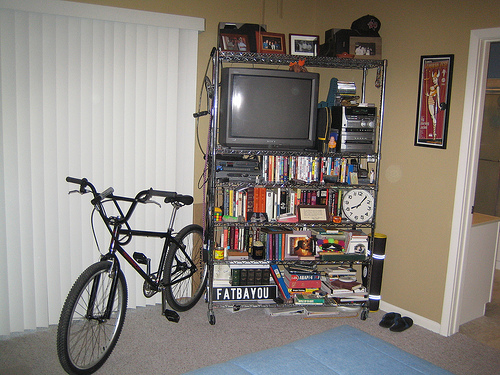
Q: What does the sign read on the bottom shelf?
A: Fatbayou.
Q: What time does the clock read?
A: Eight.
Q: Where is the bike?
A: On the left of the TV stand.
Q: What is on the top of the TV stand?
A: Picture frames.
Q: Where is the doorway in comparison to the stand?
A: On the right.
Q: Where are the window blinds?
A: Behind the bike.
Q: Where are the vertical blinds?
A: Covering the sliding door.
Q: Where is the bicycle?
A: In front of the door.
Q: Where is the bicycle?
A: In the living room.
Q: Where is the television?
A: In the corner on the cluttered shelf.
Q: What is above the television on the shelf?
A: Framed photos.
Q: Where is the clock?
A: On the shelf under the television.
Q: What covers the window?
A: Blinds.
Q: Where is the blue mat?
A: On the floor.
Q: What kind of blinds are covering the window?
A: Vertical blinds.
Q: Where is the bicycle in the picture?
A: In front of the window.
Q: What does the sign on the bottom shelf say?
A: FATBAYOU.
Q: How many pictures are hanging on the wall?
A: One.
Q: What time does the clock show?
A: 8:05.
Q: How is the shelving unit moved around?
A: With the wheels at the bottom of the unit.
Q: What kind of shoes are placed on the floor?
A: Flip-flops.